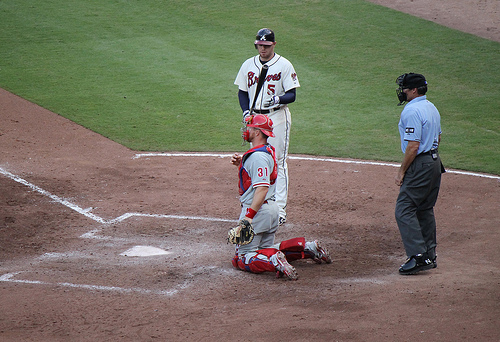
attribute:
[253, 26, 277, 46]
hat — baseball hat, black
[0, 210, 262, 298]
baseball base — diamond-shaped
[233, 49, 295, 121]
bat — black, wooden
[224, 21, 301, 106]
person — playing baseball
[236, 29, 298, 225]
batter — batting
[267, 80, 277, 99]
number — 5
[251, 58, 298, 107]
bat — baseball bat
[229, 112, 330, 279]
person — kneeling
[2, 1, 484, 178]
turf — short, green, grassy